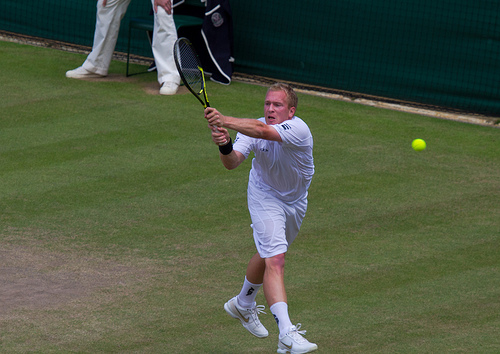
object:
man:
[202, 83, 319, 353]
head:
[264, 83, 298, 126]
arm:
[227, 119, 310, 152]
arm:
[220, 117, 267, 170]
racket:
[172, 36, 229, 144]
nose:
[268, 104, 276, 114]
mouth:
[267, 115, 275, 121]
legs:
[237, 202, 302, 319]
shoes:
[275, 326, 318, 354]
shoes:
[223, 295, 268, 339]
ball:
[411, 138, 427, 151]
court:
[2, 35, 499, 353]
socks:
[270, 302, 293, 334]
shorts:
[247, 183, 309, 258]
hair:
[268, 81, 299, 110]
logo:
[280, 339, 295, 352]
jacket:
[174, 2, 236, 83]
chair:
[122, 1, 234, 89]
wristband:
[218, 137, 233, 155]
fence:
[3, 1, 500, 132]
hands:
[204, 107, 232, 147]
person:
[66, 0, 183, 98]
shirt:
[229, 116, 314, 205]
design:
[271, 314, 281, 327]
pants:
[85, 1, 180, 90]